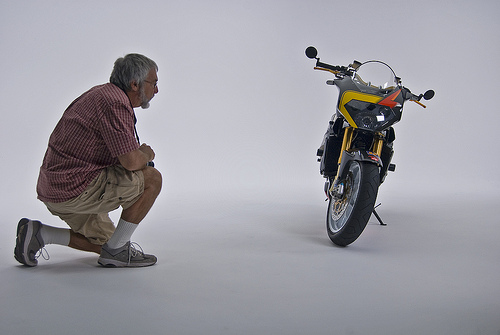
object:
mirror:
[418, 89, 435, 101]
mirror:
[304, 45, 321, 62]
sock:
[39, 223, 71, 245]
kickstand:
[372, 208, 387, 226]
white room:
[0, 0, 499, 334]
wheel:
[325, 159, 380, 247]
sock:
[106, 217, 139, 248]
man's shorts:
[40, 165, 145, 246]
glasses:
[143, 80, 158, 89]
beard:
[138, 80, 150, 110]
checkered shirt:
[34, 81, 140, 203]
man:
[13, 52, 163, 270]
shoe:
[97, 241, 158, 268]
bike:
[303, 44, 435, 248]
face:
[141, 69, 159, 105]